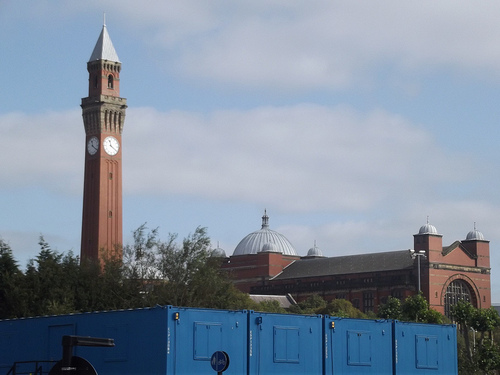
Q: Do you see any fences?
A: No, there are no fences.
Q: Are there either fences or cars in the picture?
A: No, there are no fences or cars.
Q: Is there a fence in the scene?
A: No, there are no fences.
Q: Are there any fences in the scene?
A: No, there are no fences.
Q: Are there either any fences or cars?
A: No, there are no fences or cars.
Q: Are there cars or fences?
A: No, there are no fences or cars.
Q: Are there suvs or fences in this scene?
A: No, there are no fences or suvs.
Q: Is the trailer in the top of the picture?
A: No, the trailer is in the bottom of the image.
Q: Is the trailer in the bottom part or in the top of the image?
A: The trailer is in the bottom of the image.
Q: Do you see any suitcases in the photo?
A: No, there are no suitcases.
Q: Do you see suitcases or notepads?
A: No, there are no suitcases or notepads.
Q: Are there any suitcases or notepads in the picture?
A: No, there are no suitcases or notepads.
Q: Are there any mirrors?
A: No, there are no mirrors.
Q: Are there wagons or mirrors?
A: No, there are no mirrors or wagons.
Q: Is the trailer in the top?
A: No, the trailer is in the bottom of the image.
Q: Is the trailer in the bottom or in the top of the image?
A: The trailer is in the bottom of the image.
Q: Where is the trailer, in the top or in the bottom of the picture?
A: The trailer is in the bottom of the image.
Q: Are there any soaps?
A: No, there are no soaps.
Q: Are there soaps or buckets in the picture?
A: No, there are no soaps or buckets.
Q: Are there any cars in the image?
A: No, there are no cars.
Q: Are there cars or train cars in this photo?
A: No, there are no cars or train cars.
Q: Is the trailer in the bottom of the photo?
A: Yes, the trailer is in the bottom of the image.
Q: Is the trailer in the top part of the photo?
A: No, the trailer is in the bottom of the image.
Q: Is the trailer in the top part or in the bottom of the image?
A: The trailer is in the bottom of the image.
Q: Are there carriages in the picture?
A: No, there are no carriages.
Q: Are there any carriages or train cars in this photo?
A: No, there are no carriages or train cars.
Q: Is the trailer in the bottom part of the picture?
A: Yes, the trailer is in the bottom of the image.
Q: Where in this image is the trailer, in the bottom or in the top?
A: The trailer is in the bottom of the image.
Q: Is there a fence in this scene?
A: No, there are no fences.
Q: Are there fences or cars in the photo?
A: No, there are no fences or cars.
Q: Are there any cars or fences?
A: No, there are no fences or cars.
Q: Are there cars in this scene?
A: No, there are no cars.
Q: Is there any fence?
A: No, there are no fences.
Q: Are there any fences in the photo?
A: No, there are no fences.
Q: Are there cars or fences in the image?
A: No, there are no fences or cars.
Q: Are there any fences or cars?
A: No, there are no fences or cars.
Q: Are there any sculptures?
A: No, there are no sculptures.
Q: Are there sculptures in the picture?
A: No, there are no sculptures.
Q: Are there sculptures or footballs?
A: No, there are no sculptures or footballs.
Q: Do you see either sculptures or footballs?
A: No, there are no sculptures or footballs.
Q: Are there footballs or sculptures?
A: No, there are no sculptures or footballs.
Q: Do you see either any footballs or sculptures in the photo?
A: No, there are no sculptures or footballs.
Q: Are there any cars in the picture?
A: No, there are no cars.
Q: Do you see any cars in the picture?
A: No, there are no cars.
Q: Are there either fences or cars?
A: No, there are no cars or fences.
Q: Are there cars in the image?
A: No, there are no cars.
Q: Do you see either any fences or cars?
A: No, there are no cars or fences.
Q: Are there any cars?
A: No, there are no cars.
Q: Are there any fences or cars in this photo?
A: No, there are no cars or fences.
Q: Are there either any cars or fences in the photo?
A: No, there are no cars or fences.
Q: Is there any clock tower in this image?
A: Yes, there is a clock tower.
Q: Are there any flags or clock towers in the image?
A: Yes, there is a clock tower.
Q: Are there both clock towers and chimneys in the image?
A: No, there is a clock tower but no chimneys.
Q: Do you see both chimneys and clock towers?
A: No, there is a clock tower but no chimneys.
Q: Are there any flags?
A: No, there are no flags.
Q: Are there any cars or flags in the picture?
A: No, there are no flags or cars.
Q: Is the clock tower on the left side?
A: Yes, the clock tower is on the left of the image.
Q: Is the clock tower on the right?
A: No, the clock tower is on the left of the image.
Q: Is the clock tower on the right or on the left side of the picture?
A: The clock tower is on the left of the image.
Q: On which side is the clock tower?
A: The clock tower is on the left of the image.